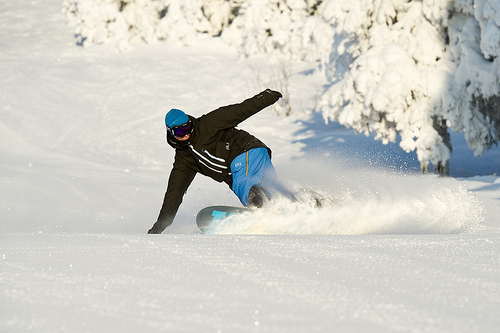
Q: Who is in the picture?
A: A man.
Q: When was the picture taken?
A: Daytime.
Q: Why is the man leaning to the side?
A: Because he's about to fall over.